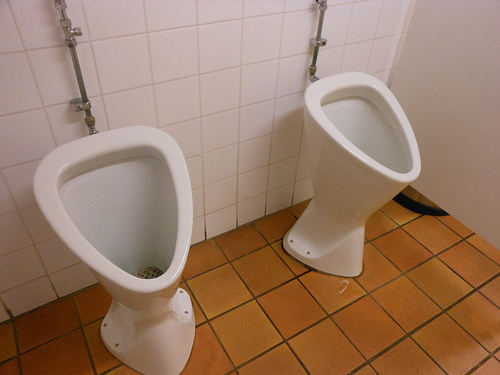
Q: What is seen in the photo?
A: Toilets.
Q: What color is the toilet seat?
A: White.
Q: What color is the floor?
A: Brown.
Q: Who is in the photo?
A: Nobody.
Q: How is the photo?
A: Clear.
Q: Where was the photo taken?
A: In a bathroom.